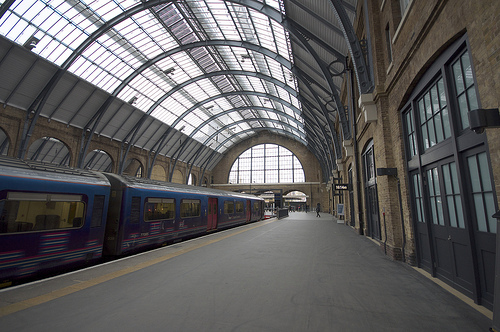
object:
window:
[278, 167, 294, 184]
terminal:
[210, 133, 328, 212]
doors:
[395, 28, 497, 312]